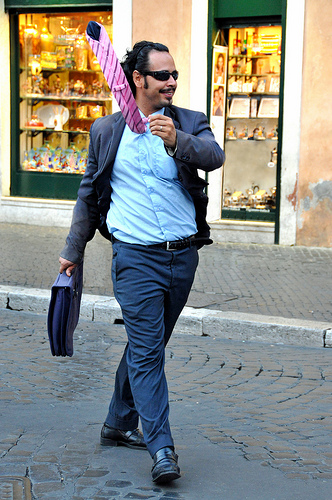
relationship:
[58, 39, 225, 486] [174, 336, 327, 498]
man on street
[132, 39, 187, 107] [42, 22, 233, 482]
face of person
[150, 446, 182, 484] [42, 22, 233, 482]
shoe of person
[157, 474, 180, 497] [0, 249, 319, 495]
shadow on ground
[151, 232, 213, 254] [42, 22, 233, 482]
belt of person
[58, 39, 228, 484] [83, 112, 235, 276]
man wearing suit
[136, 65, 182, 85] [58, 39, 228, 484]
spects of man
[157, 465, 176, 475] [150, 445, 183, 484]
front of foot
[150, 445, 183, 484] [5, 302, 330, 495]
foot lifted off ground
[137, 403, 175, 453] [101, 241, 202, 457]
wrinkles on bottom of pants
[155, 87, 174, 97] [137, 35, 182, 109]
smile on face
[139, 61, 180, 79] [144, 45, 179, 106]
sunglasses on face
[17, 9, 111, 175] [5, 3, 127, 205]
various objects on display in window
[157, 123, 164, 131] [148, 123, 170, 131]
silver ring around finger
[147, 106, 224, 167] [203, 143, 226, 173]
arm bent at elbow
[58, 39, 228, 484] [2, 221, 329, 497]
man walking down street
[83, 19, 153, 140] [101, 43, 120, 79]
tie has stripes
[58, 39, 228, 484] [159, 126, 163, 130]
man is wearing a ring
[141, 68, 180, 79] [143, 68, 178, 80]
pair of sunglasses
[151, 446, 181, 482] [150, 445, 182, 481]
shoe on a foot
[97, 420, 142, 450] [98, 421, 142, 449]
shoe on a foot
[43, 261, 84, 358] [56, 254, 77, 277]
briefcase being held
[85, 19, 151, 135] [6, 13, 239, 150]
tie flowing in the wind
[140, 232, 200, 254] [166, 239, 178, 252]
belt with buckle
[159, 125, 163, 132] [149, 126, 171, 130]
silver ring on a finger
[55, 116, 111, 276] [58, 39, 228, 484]
arm of a man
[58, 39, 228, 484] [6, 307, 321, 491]
man walking on the street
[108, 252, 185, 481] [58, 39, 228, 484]
leg of a man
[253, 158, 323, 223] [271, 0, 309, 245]
paint peeling on window trim